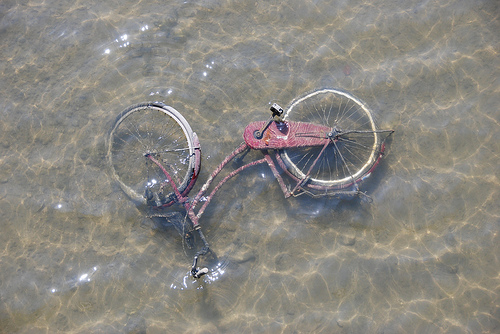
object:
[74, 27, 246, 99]
reflections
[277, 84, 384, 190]
wheel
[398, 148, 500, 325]
ground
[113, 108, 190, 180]
spokes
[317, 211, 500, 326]
ground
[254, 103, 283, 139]
pedal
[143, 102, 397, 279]
frame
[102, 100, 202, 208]
wheel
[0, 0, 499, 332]
water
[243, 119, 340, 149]
cover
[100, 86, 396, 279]
bicycle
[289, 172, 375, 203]
fender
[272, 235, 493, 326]
waves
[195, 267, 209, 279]
handle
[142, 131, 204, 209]
fender